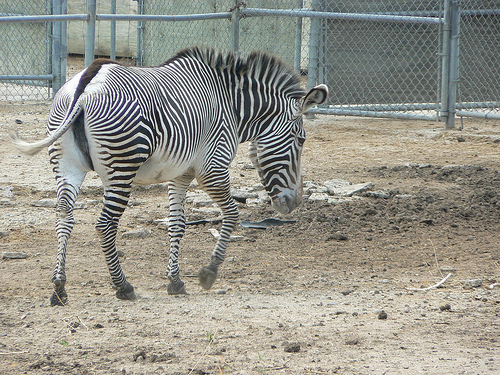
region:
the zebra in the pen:
[25, 20, 332, 316]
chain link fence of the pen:
[1, 0, 491, 117]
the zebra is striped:
[13, 32, 353, 314]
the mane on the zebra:
[206, 46, 302, 96]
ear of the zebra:
[294, 76, 347, 128]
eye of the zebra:
[286, 123, 310, 150]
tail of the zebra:
[6, 99, 78, 168]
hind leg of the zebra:
[84, 96, 161, 320]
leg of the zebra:
[194, 151, 254, 293]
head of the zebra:
[239, 63, 339, 235]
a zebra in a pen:
[21, 37, 323, 304]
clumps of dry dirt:
[337, 117, 498, 373]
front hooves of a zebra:
[158, 262, 220, 299]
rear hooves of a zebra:
[50, 274, 139, 308]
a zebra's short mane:
[172, 42, 307, 91]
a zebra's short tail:
[15, 103, 77, 161]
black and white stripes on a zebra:
[107, 66, 233, 171]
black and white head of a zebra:
[246, 69, 320, 216]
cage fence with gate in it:
[340, 0, 497, 122]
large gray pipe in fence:
[96, 9, 452, 24]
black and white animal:
[14, 26, 329, 311]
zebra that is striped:
[6, 35, 333, 322]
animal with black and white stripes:
[14, 54, 343, 304]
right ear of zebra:
[298, 71, 330, 115]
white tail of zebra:
[13, 113, 83, 160]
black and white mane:
[168, 41, 304, 94]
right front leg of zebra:
[190, 171, 238, 296]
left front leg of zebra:
[156, 180, 193, 297]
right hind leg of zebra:
[95, 165, 140, 305]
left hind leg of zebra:
[44, 173, 73, 310]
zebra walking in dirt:
[7, 41, 334, 309]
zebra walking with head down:
[10, 36, 340, 306]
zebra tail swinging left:
[6, 100, 80, 157]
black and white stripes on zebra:
[39, 45, 328, 311]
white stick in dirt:
[402, 235, 457, 295]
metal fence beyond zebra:
[2, 2, 498, 134]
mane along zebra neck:
[170, 38, 312, 98]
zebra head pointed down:
[247, 78, 327, 215]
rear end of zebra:
[10, 60, 147, 308]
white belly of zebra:
[127, 147, 209, 189]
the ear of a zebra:
[295, 78, 335, 115]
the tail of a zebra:
[9, 105, 79, 154]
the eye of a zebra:
[293, 133, 308, 153]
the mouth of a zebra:
[281, 189, 295, 219]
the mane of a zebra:
[188, 41, 307, 99]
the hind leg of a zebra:
[92, 122, 149, 307]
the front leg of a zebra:
[161, 171, 196, 303]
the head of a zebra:
[243, 47, 329, 222]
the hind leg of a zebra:
[40, 136, 88, 311]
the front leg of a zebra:
[189, 149, 243, 294]